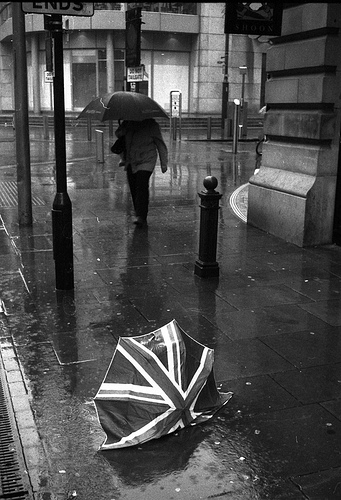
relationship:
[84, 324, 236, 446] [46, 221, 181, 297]
umbrella on top of ground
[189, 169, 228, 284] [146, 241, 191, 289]
post attached to sidewalk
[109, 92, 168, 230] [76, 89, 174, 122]
person holding umbrella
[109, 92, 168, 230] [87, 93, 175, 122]
person underneath umbrella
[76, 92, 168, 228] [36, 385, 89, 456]
person walks in rain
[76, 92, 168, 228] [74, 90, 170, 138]
person under umbrella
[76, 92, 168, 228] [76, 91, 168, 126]
person carrying umbrella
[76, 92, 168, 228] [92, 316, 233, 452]
person walks toward umbrella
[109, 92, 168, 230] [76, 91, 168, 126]
person holding umbrella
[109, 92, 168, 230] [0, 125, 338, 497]
person walking on sidewalk